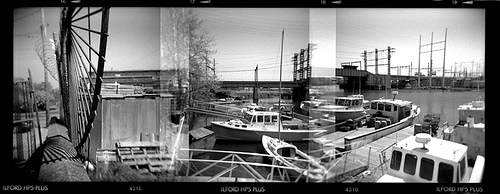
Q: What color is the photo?
A: Black and white.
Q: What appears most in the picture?
A: Boats.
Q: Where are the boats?
A: At the dock.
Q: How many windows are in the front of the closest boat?
A: Four.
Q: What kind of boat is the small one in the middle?
A: Sail.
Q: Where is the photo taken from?
A: Another boat.